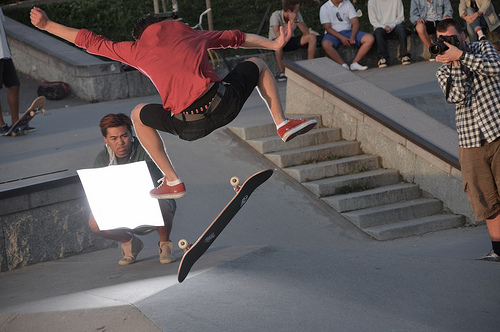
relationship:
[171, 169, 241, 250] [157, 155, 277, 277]
wheels on skateboard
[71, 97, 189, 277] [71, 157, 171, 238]
man has paper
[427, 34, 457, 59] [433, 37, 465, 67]
camera on hand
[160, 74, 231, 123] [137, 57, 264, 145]
belt on shorts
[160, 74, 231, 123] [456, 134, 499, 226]
belt on shorts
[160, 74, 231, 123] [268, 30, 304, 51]
belt on shorts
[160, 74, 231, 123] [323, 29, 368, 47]
belt on shorts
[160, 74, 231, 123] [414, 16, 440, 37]
belt on shorts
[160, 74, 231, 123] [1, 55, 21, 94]
belt on shorts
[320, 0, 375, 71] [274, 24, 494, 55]
man on stoop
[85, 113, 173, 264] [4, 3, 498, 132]
man in air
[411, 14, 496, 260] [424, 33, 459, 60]
man has camera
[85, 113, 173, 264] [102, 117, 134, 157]
man has head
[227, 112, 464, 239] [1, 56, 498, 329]
stairs in area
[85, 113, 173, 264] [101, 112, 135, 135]
man has hair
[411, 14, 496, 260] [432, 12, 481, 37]
man has hair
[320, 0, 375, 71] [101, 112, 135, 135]
man has hair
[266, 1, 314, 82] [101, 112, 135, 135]
man has hair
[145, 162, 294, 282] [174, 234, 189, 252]
skateboard has wheel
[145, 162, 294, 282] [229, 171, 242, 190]
skateboard has wheel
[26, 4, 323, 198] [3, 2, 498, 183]
person in air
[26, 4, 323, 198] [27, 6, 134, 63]
person extends arm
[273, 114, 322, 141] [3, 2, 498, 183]
shoe in air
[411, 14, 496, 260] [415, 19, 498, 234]
man holding camera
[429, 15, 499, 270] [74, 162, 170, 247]
man holding mirror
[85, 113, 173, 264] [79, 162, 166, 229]
man holding mirror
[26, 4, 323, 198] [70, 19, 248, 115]
person wears shirt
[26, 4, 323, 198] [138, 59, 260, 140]
person wearing black shorts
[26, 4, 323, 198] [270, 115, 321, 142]
person wearing shoe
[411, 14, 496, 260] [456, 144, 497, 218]
man wearing shorts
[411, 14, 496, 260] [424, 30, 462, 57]
man holding camera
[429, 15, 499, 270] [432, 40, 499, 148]
man wearing checkered shirt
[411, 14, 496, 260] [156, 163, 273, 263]
man taking picture of skater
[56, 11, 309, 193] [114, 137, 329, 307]
person doing trick on skateboard